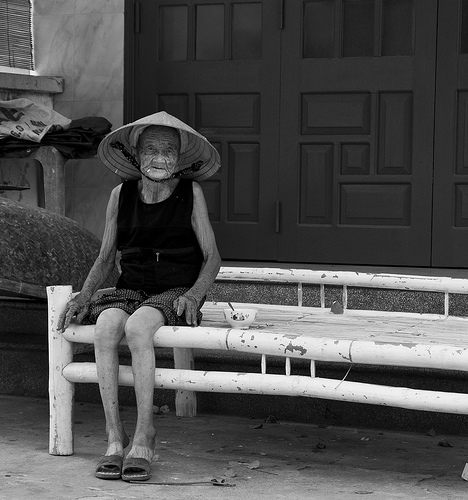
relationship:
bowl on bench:
[220, 302, 258, 327] [30, 263, 467, 459]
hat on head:
[99, 109, 222, 183] [135, 127, 181, 180]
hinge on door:
[272, 198, 282, 235] [100, 0, 463, 265]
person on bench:
[55, 124, 222, 470] [37, 262, 466, 481]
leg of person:
[123, 306, 169, 463] [55, 110, 221, 484]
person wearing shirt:
[55, 124, 222, 470] [114, 174, 204, 295]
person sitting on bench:
[55, 124, 222, 470] [11, 230, 466, 437]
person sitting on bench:
[55, 124, 222, 470] [46, 266, 466, 455]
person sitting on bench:
[55, 124, 222, 470] [30, 263, 467, 459]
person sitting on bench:
[55, 124, 222, 470] [39, 232, 466, 470]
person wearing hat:
[55, 124, 222, 470] [99, 109, 222, 183]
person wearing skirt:
[55, 124, 222, 470] [97, 181, 209, 320]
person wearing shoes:
[55, 124, 222, 470] [94, 453, 123, 480]